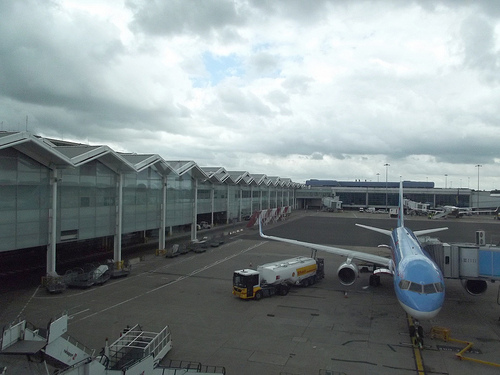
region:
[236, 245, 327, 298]
fuel truck fueling up airplane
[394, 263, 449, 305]
cockpit area of airplane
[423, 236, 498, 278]
passenger loading tunnel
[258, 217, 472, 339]
blue and white plane refueling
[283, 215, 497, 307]
blue and white plane with passenger tunnel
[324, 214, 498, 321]
blue and white plane with 2 turbine engines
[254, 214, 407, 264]
white wing with tip curved upwards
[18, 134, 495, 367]
outside of airport with plane refueling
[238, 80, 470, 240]
overcast skies above airport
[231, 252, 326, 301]
white and yellow fuel truck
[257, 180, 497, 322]
blue plane is parked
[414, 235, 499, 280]
jet way connected to plane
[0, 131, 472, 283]
airport next to plane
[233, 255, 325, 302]
yellow and white truck next to plane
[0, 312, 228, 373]
staircases in front of airport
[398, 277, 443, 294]
four windows at front of plane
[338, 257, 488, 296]
two engines on plane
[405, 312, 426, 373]
yellow line under plane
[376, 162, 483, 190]
lights behind plane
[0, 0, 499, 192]
sky is cloudy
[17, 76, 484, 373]
Picture of an airport.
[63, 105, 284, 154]
The sky is dark, cloudy sky.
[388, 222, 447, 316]
Fuselage of airplane is light blue.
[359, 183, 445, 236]
The tail of an airplane.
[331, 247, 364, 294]
Right front engine on airplane.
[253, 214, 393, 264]
The right side wing on airplane.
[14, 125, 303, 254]
A long building to the left.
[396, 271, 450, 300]
Cockpit windows of an airplane.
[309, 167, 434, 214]
Building in the background.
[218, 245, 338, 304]
A gas truck to fuel the airplane.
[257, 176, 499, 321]
a blue and white airplane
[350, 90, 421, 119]
white clouds in sky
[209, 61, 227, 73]
light blue sky between clouds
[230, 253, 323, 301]
yellow and white truck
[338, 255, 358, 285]
engine of plane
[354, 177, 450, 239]
tail of airplane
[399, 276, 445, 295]
four windows of airplane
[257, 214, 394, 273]
wing of an airplane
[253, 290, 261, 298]
large wheel of truck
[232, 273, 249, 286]
large windshield of truck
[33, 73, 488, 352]
Scene at a commercial airport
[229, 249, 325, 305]
An airline fuel tanker on the tarmac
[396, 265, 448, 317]
The cockpit of a large plane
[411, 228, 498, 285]
Boarding ramp connected to plane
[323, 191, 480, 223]
Airport equipment on the tarmac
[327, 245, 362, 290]
Engine of a jet engine plane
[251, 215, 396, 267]
The right wing of a plane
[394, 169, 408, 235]
The tail fine of a large plane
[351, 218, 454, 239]
Horizontal stabilizers on a large plane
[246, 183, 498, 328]
A large plane parked on the tarmac